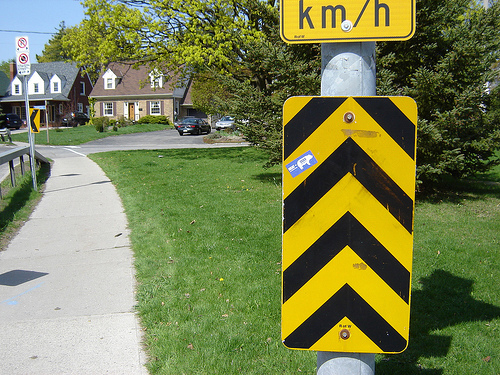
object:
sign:
[281, 96, 418, 354]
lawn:
[0, 123, 173, 146]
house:
[89, 60, 220, 128]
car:
[175, 118, 211, 136]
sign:
[28, 107, 42, 135]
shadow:
[37, 179, 112, 193]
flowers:
[58, 1, 276, 89]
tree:
[58, 1, 279, 96]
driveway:
[80, 125, 212, 146]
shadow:
[59, 173, 81, 176]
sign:
[15, 35, 31, 77]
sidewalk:
[1, 156, 146, 374]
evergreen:
[193, 0, 500, 193]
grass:
[87, 146, 500, 375]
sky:
[0, 1, 258, 65]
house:
[2, 60, 92, 129]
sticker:
[285, 150, 318, 179]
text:
[298, 0, 389, 29]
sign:
[277, 0, 417, 45]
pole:
[319, 41, 377, 96]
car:
[61, 112, 88, 128]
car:
[216, 115, 248, 131]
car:
[0, 113, 24, 130]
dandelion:
[219, 277, 225, 283]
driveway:
[11, 125, 73, 135]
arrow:
[30, 109, 38, 132]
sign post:
[22, 77, 37, 193]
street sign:
[33, 105, 45, 109]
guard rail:
[0, 146, 31, 188]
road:
[0, 146, 31, 182]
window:
[15, 84, 20, 94]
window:
[34, 83, 39, 93]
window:
[54, 82, 58, 91]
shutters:
[150, 101, 160, 114]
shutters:
[103, 102, 112, 115]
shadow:
[373, 270, 500, 374]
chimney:
[9, 60, 17, 80]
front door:
[129, 103, 135, 120]